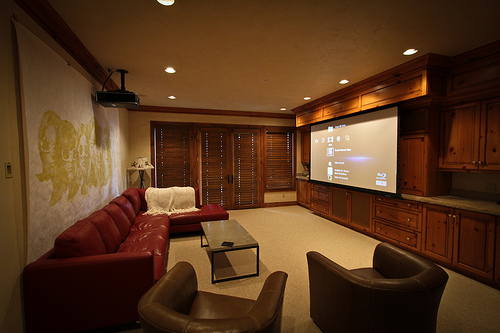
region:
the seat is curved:
[318, 230, 445, 308]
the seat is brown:
[158, 262, 290, 328]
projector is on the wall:
[300, 123, 413, 190]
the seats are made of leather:
[85, 185, 219, 262]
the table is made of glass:
[192, 215, 269, 276]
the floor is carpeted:
[262, 210, 332, 244]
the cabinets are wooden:
[410, 115, 499, 254]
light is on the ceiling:
[163, 68, 183, 103]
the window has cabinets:
[173, 130, 279, 200]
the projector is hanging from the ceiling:
[104, 81, 146, 118]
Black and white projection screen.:
[301, 105, 411, 200]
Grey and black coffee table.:
[195, 215, 271, 283]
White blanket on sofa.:
[144, 178, 199, 221]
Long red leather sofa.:
[24, 179, 230, 326]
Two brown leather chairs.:
[139, 245, 457, 328]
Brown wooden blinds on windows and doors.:
[147, 113, 297, 206]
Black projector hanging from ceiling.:
[90, 55, 135, 110]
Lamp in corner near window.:
[125, 151, 155, 187]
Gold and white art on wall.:
[10, 15, 125, 257]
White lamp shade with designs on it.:
[128, 152, 156, 172]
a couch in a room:
[91, 169, 221, 277]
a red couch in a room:
[69, 125, 264, 295]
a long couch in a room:
[48, 169, 230, 324]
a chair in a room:
[294, 208, 484, 325]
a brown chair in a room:
[296, 220, 448, 303]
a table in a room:
[181, 173, 285, 273]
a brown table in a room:
[172, 205, 289, 288]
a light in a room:
[147, 50, 219, 100]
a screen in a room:
[292, 111, 448, 191]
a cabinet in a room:
[388, 118, 483, 200]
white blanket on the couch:
[144, 185, 199, 213]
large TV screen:
[308, 105, 398, 195]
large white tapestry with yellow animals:
[10, 15, 125, 262]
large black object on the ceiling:
[95, 65, 138, 108]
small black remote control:
[220, 240, 232, 245]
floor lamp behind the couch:
[127, 156, 154, 186]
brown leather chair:
[305, 240, 450, 330]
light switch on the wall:
[3, 160, 13, 179]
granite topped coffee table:
[199, 218, 260, 283]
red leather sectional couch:
[18, 186, 230, 327]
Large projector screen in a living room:
[303, 100, 406, 196]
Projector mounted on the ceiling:
[87, 61, 145, 114]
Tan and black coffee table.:
[193, 216, 266, 285]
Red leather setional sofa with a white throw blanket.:
[16, 187, 236, 324]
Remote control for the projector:
[217, 238, 240, 250]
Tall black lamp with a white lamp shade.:
[125, 157, 157, 190]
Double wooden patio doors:
[197, 123, 265, 210]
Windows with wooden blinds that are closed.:
[146, 117, 300, 202]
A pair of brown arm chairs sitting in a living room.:
[126, 242, 449, 331]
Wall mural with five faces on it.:
[21, 51, 145, 269]